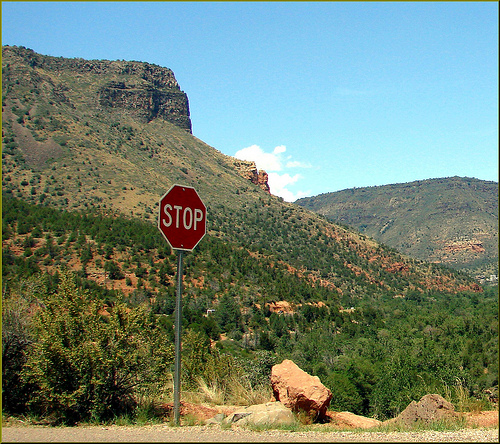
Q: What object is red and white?
A: Stop sign.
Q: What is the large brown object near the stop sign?
A: Rock.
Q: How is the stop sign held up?
A: With a gray metal pole.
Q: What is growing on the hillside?
A: Bushes and trees.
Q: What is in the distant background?
A: Mountains.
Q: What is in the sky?
A: Clouds.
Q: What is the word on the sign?
A: STOP.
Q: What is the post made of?
A: Metal.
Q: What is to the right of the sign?
A: Rocks.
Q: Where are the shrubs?
A: Hill.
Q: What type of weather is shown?
A: Mostly sunny.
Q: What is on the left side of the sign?
A: Road.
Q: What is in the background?
A: Hills.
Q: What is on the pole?
A: A stop sign.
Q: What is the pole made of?
A: Metal.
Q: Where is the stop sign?
A: On the pole.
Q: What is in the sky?
A: Clouds.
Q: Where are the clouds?
A: In the sky.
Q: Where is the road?
A: Next to the stop sign.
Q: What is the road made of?
A: Asphalt.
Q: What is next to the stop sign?
A: The road.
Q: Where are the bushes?
A: Behind the sign.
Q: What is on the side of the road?
A: Boulders.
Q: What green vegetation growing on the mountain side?
A: Grass and trees.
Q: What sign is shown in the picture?
A: Stop sign.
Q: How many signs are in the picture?
A: One.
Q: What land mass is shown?
A: Mesa.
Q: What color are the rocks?
A: Orange.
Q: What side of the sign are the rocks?
A: Right.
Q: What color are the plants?
A: Green.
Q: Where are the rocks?
A: Beside the road.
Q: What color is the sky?
A: Blue.